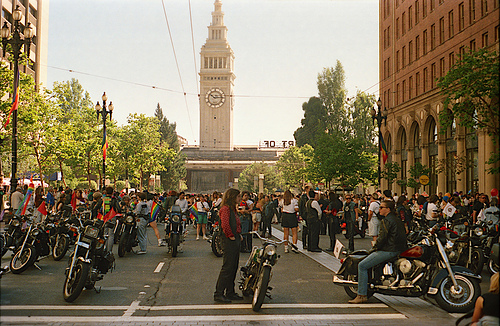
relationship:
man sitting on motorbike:
[364, 200, 423, 312] [336, 193, 475, 299]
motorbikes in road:
[7, 200, 127, 299] [311, 263, 319, 284]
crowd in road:
[34, 185, 414, 275] [311, 263, 319, 284]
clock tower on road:
[195, 13, 240, 144] [311, 263, 319, 284]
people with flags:
[427, 199, 472, 221] [445, 210, 453, 220]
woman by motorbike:
[218, 204, 244, 242] [336, 193, 475, 299]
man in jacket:
[364, 200, 423, 312] [371, 211, 410, 254]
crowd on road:
[34, 185, 414, 275] [311, 263, 319, 284]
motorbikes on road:
[7, 200, 127, 299] [311, 263, 319, 284]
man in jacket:
[364, 200, 423, 312] [385, 218, 390, 219]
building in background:
[189, 150, 267, 188] [246, 120, 250, 125]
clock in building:
[209, 78, 236, 120] [189, 150, 267, 188]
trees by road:
[121, 132, 186, 188] [311, 263, 319, 284]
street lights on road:
[75, 86, 121, 121] [311, 263, 319, 284]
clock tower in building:
[195, 13, 240, 144] [189, 150, 267, 188]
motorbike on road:
[336, 193, 475, 299] [311, 263, 319, 284]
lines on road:
[128, 284, 220, 326] [311, 263, 319, 284]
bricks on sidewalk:
[404, 303, 421, 316] [310, 249, 332, 254]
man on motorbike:
[364, 200, 423, 312] [336, 193, 475, 299]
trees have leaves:
[121, 132, 186, 188] [476, 49, 492, 61]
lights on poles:
[1, 6, 40, 44] [93, 124, 114, 174]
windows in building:
[384, 112, 458, 143] [440, 24, 456, 44]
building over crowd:
[189, 150, 267, 188] [34, 185, 414, 275]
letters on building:
[251, 135, 305, 155] [189, 150, 267, 188]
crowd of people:
[34, 185, 414, 275] [427, 199, 472, 221]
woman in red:
[218, 204, 244, 242] [223, 203, 225, 213]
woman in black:
[218, 204, 244, 242] [224, 273, 231, 278]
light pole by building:
[367, 117, 399, 188] [440, 24, 456, 44]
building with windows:
[440, 24, 456, 44] [384, 112, 458, 143]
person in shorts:
[198, 193, 214, 232] [195, 192, 212, 240]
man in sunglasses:
[364, 200, 423, 312] [372, 205, 404, 212]